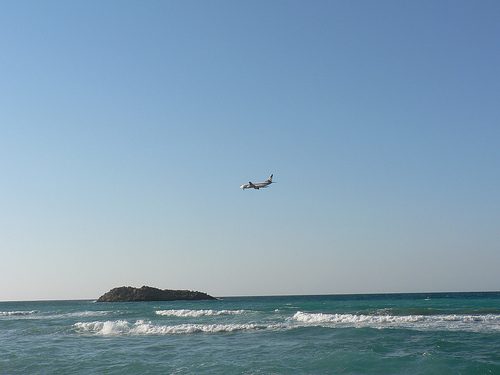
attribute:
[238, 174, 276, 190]
plane — flying, landing, small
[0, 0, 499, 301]
sky — blue, clear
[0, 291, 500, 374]
ocean — calm, blue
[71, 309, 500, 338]
wave — smooth